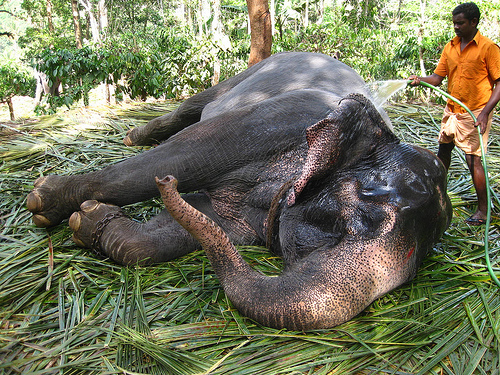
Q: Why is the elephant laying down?
A: To be washed.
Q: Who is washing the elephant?
A: A man.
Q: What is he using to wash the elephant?
A: A hose.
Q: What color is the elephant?
A: Brown and black.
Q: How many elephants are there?
A: One.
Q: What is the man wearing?
A: Shirt and shorts.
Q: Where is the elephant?
A: In the grass.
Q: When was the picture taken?
A: In the daytime.